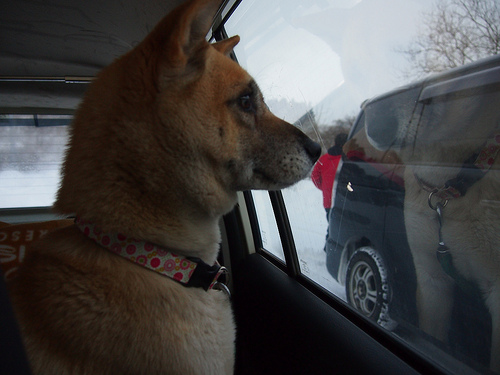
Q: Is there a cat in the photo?
A: No, there are no cats.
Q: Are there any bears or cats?
A: No, there are no cats or bears.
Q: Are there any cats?
A: No, there are no cats.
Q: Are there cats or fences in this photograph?
A: No, there are no cats or fences.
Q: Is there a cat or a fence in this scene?
A: No, there are no cats or fences.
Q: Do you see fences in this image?
A: No, there are no fences.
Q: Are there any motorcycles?
A: No, there are no motorcycles.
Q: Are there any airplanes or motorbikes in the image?
A: No, there are no motorbikes or airplanes.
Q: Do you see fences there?
A: No, there are no fences.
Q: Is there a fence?
A: No, there are no fences.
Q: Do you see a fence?
A: No, there are no fences.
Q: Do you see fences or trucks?
A: No, there are no fences or trucks.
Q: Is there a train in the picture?
A: No, there are no trains.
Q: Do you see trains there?
A: No, there are no trains.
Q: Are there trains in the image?
A: No, there are no trains.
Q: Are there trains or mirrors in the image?
A: No, there are no trains or mirrors.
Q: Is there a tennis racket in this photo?
A: No, there are no rackets.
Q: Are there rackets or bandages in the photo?
A: No, there are no rackets or bandages.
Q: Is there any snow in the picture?
A: Yes, there is snow.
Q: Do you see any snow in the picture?
A: Yes, there is snow.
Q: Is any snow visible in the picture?
A: Yes, there is snow.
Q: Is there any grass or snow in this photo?
A: Yes, there is snow.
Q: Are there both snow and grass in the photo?
A: No, there is snow but no grass.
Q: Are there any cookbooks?
A: No, there are no cookbooks.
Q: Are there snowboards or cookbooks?
A: No, there are no cookbooks or snowboards.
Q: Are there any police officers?
A: No, there are no police officers.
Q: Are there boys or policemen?
A: No, there are no policemen or boys.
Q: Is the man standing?
A: Yes, the man is standing.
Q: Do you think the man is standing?
A: Yes, the man is standing.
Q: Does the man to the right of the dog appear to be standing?
A: Yes, the man is standing.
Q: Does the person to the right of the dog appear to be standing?
A: Yes, the man is standing.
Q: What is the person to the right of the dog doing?
A: The man is standing.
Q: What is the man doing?
A: The man is standing.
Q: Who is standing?
A: The man is standing.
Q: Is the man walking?
A: No, the man is standing.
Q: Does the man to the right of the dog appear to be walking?
A: No, the man is standing.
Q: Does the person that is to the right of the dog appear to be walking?
A: No, the man is standing.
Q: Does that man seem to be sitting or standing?
A: The man is standing.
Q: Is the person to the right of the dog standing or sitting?
A: The man is standing.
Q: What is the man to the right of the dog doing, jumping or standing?
A: The man is standing.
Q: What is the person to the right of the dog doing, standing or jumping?
A: The man is standing.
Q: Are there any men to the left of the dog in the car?
A: No, the man is to the right of the dog.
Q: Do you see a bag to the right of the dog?
A: No, there is a man to the right of the dog.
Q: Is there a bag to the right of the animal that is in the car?
A: No, there is a man to the right of the dog.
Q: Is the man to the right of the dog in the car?
A: Yes, the man is to the right of the dog.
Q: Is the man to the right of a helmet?
A: No, the man is to the right of the dog.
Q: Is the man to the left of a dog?
A: No, the man is to the right of a dog.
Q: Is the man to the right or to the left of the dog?
A: The man is to the right of the dog.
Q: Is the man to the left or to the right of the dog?
A: The man is to the right of the dog.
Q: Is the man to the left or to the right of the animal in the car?
A: The man is to the right of the dog.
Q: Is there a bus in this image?
A: No, there are no buses.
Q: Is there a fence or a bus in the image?
A: No, there are no buses or fences.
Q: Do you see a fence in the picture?
A: No, there are no fences.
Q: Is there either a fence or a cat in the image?
A: No, there are no fences or cats.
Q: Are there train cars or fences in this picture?
A: No, there are no fences or train cars.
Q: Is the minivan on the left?
A: No, the minivan is on the right of the image.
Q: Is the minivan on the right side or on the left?
A: The minivan is on the right of the image.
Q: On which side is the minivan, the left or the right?
A: The minivan is on the right of the image.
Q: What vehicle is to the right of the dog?
A: The vehicle is a minivan.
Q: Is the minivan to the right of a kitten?
A: No, the minivan is to the right of the dog.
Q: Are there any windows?
A: Yes, there is a window.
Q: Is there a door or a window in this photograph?
A: Yes, there is a window.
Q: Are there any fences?
A: No, there are no fences.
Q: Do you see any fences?
A: No, there are no fences.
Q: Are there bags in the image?
A: No, there are no bags.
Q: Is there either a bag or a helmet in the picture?
A: No, there are no bags or helmets.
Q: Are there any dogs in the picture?
A: Yes, there is a dog.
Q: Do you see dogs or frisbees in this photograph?
A: Yes, there is a dog.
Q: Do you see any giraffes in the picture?
A: No, there are no giraffes.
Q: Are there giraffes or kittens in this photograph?
A: No, there are no giraffes or kittens.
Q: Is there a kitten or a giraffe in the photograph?
A: No, there are no giraffes or kittens.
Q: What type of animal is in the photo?
A: The animal is a dog.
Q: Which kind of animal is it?
A: The animal is a dog.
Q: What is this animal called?
A: This is a dog.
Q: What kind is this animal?
A: This is a dog.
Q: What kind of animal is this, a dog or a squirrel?
A: This is a dog.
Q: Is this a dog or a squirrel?
A: This is a dog.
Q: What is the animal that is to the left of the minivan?
A: The animal is a dog.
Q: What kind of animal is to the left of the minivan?
A: The animal is a dog.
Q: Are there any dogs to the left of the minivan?
A: Yes, there is a dog to the left of the minivan.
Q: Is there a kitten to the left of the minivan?
A: No, there is a dog to the left of the minivan.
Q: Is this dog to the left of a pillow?
A: No, the dog is to the left of the minivan.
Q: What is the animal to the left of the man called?
A: The animal is a dog.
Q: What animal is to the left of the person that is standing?
A: The animal is a dog.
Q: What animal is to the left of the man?
A: The animal is a dog.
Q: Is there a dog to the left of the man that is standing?
A: Yes, there is a dog to the left of the man.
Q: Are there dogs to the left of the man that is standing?
A: Yes, there is a dog to the left of the man.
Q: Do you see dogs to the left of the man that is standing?
A: Yes, there is a dog to the left of the man.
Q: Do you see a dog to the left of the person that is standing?
A: Yes, there is a dog to the left of the man.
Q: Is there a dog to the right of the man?
A: No, the dog is to the left of the man.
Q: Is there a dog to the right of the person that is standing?
A: No, the dog is to the left of the man.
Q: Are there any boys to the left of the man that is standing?
A: No, there is a dog to the left of the man.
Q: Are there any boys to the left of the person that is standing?
A: No, there is a dog to the left of the man.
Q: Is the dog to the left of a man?
A: Yes, the dog is to the left of a man.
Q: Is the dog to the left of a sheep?
A: No, the dog is to the left of a man.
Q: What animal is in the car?
A: The dog is in the car.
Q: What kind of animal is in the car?
A: The animal is a dog.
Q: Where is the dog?
A: The dog is in the car.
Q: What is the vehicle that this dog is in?
A: The vehicle is a car.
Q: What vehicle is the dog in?
A: The dog is in the car.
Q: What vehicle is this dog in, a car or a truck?
A: The dog is in a car.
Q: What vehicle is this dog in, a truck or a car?
A: The dog is in a car.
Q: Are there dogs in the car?
A: Yes, there is a dog in the car.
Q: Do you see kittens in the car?
A: No, there is a dog in the car.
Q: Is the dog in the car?
A: Yes, the dog is in the car.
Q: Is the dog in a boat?
A: No, the dog is in the car.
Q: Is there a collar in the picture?
A: Yes, there is a collar.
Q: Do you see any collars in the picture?
A: Yes, there is a collar.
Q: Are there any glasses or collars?
A: Yes, there is a collar.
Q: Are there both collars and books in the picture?
A: No, there is a collar but no books.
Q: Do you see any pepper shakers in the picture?
A: No, there are no pepper shakers.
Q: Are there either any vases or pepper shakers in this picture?
A: No, there are no pepper shakers or vases.